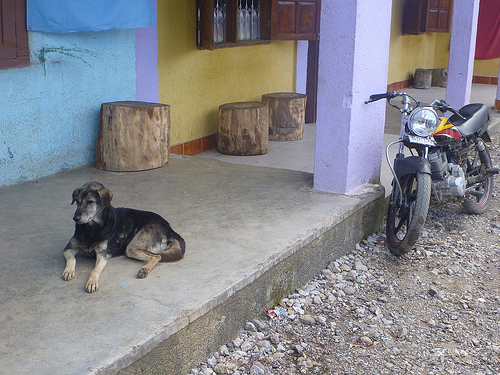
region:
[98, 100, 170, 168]
a log of wood on cement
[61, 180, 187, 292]
a dog laying on a cement floor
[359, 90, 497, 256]
a motorcycle parked in front of a white pillar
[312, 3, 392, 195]
a white pillar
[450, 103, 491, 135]
black and silver seat of a motorcycle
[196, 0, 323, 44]
opened wooden shutters of a window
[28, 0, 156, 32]
a blue sheet hanging on a wall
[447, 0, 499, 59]
a red sheet hanging on a yellow wall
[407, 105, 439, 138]
a motorcycle's headlight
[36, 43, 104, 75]
scratches on a green painted wall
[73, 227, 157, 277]
the dog is sitting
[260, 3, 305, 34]
the door is open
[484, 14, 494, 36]
the curtain is red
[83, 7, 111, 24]
the curtain is blue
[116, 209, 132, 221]
the dog is black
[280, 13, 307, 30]
the door is brown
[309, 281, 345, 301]
the rocks are gray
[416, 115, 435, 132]
the light is off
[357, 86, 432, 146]
the bike is leaning on the pillar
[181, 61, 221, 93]
the wall is yellow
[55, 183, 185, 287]
the dog is laying down.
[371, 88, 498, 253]
the motorcycle is propped against the post.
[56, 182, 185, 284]
the dog is black and tan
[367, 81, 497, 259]
the motorcycle is on gravel.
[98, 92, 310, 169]
three tree stumps on porch.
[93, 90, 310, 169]
three tree stumps about the same size.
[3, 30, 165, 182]
the wall is blue.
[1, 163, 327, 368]
the porch is made of concrete.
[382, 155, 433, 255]
motorcycle tire is black.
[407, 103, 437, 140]
headlight on the motorcycle.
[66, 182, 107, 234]
head of a dog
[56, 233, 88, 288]
leg of a dog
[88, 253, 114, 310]
leg of a dog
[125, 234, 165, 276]
leg of a dog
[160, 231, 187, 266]
tail of a dog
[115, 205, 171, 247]
body of a dog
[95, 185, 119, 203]
ear of a dog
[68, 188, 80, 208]
ear of a dog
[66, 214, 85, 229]
nose of a dog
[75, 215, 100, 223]
mouth of a dog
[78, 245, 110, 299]
leg of a dog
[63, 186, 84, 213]
ear of a dog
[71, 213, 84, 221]
nose of a dog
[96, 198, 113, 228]
neck of a dog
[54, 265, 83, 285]
paw of a dog